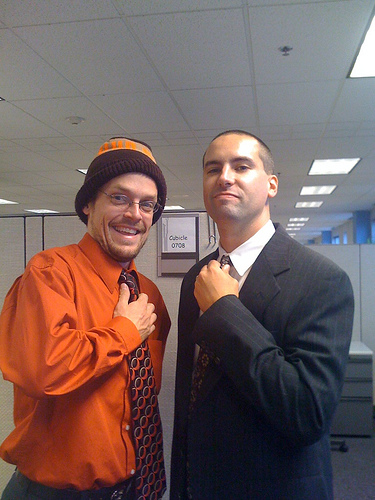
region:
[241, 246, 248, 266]
MAN HAS ON WHITE SHIRT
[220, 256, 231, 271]
MAN HAND ON THE TIE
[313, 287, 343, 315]
MAN HAS ON A SUIT COAT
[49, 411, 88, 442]
MAN HAS ON A ORANGE SHIRT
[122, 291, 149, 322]
MAN HAS HAND ON TIE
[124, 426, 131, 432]
WHITE BUTTONS ON THE SHIRT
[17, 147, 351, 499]
two men standing for a pose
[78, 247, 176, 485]
the tie has a design on it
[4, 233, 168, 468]
the shirt is orange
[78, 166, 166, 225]
the man is wearing glasses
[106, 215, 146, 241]
the mouth is open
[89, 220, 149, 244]
the teeth are showing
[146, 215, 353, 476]
man on the right is wearing a suit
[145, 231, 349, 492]
the suit is pin striped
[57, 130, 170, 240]
man is wearing a hat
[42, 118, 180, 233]
the hat is brown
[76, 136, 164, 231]
man wearing a brown and orange hat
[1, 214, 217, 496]
gray partitions in an office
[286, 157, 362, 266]
white fluorescent lights on the ceiling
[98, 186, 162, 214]
a man wearing glasses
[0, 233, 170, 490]
man wearing an orange button-down shirt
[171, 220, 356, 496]
man wearing a blue jacket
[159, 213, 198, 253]
a panel on a partition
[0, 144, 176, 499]
Man wearing a orange shirt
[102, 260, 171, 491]
Tie around the man's neck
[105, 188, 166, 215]
Glasses on the man's face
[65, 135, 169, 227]
Hat on the man's head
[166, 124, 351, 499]
Man wearing a black jacket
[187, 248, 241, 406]
Tie around the man's neck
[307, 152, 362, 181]
Light in the ceiling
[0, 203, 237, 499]
Cubicle behind the men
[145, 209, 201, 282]
Paper on the cubicle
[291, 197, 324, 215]
Light in the ceiling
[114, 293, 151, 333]
the hand of a man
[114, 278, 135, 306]
the thumb of a man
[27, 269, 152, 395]
the arm of a man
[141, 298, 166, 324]
the fingers of a man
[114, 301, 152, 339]
the veins of a man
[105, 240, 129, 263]
the chin of a man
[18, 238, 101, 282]
the shoulder of a man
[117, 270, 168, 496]
Colorful tie with circles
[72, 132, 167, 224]
Orange, brown, and grey knit hat.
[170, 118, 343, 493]
Business man adjusting tie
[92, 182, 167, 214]
Small, circular glasses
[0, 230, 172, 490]
Bright orange long sleeve shirt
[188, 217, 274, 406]
Clean, ironed, white dress shirt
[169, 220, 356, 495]
Pinstriped blue business jacket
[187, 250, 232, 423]
Flowered business tie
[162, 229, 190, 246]
Black wall writing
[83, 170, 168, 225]
Man wearing glasses with a metal frame.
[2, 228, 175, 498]
An orange dress shirt and tie.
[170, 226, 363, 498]
A grey suit and tie.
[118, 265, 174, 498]
A tie with orange and white circles.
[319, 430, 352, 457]
Part of a chair wheel.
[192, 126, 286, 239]
A man with a close shave and short hair style.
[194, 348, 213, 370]
A yellow flower on a tie.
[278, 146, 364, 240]
The lights on the ceiling are turned on.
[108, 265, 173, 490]
orange black and gray tie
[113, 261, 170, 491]
orange black and gray tie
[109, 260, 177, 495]
orange black and gray tie